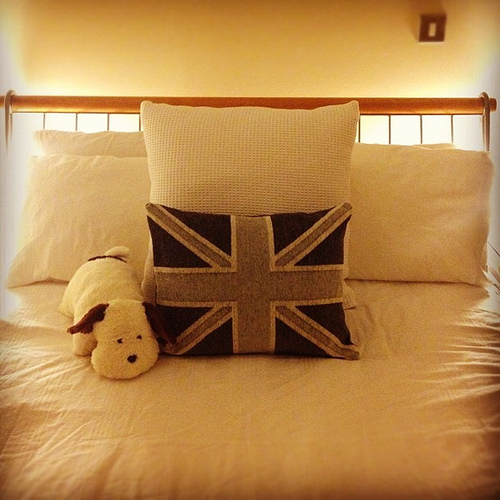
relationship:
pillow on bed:
[108, 64, 395, 360] [8, 108, 493, 468]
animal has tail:
[56, 245, 177, 380] [96, 231, 137, 261]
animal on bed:
[56, 245, 177, 380] [8, 108, 493, 468]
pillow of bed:
[108, 64, 395, 360] [8, 108, 493, 468]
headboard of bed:
[17, 61, 488, 213] [8, 108, 493, 468]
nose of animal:
[130, 347, 149, 361] [56, 245, 177, 380]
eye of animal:
[90, 316, 153, 356] [56, 245, 177, 380]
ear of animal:
[78, 293, 118, 343] [56, 245, 177, 380]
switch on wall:
[411, 13, 450, 57] [180, 17, 410, 96]